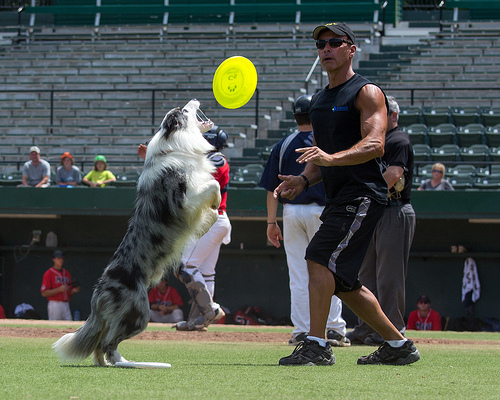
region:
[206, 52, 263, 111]
The frisbee is yellow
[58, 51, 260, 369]
The dog is leaping up to catch the frisbee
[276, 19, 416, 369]
The man is standing on grass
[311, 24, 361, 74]
Man wearing a black hat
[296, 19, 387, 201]
Man wearing a black shirt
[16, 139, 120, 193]
People sitting in the stands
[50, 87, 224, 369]
The dog is grey, black, and white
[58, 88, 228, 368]
The dog is on its hind legs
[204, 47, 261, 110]
The frisbee is in the air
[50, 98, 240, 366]
The dog has a long coat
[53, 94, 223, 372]
A dog on its hind legs.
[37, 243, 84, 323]
A person in a baseball uniform.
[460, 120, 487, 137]
A empty seat in the bleachers.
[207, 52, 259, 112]
A Frisbee in the air.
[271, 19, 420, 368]
A man wearing black shoes.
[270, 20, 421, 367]
A man wearing a black hat.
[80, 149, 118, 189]
A person wearing a yellow shirt.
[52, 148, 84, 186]
A person wearing a orange hat.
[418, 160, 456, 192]
A person sitting in the bleachers.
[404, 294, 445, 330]
A person sitting in the dugout.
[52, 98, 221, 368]
large fluffy grey and white dog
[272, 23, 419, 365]
muscular athletic looking man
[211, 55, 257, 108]
yellow frisbee hanging in mid air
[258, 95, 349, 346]
man in blue and white baseball uniform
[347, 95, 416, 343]
man with grey hair in grey slacks and black shirt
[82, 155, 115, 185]
child spectator with yellow shirt and green hat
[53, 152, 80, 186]
woman spectator with grey shirt and orange hat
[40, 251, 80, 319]
man in red and white baseball outfit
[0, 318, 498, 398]
green grassy sports field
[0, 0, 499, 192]
bleachers are almost empty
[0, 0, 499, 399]
the interior of a baseball stadium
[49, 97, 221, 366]
a dog catching a frisbee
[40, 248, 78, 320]
a baseball player in the bullpen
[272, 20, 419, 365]
a man standing on the field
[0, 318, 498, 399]
the baseball field's ground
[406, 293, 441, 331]
a baseball player sitting in the bullpen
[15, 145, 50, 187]
a man sitting in the stands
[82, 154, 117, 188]
a kid sitting in the stands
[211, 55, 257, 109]
an airborne yellow frisbee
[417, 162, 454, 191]
a person sitting in the stands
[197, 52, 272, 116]
disc in the air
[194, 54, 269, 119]
yellow disc with a smily face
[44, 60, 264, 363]
dog trying to catch the disc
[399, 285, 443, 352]
man sitting on the bench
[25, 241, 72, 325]
man with red shirt watching dog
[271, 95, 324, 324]
player with his back to man and dog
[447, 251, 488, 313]
towel hung up in dugout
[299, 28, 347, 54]
person wearing sunglasses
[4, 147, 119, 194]
three people watching dog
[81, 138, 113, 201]
girl in yellow shirt and green cap